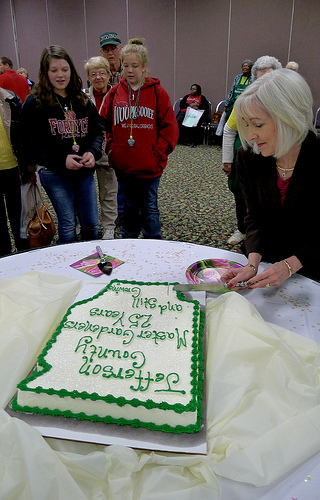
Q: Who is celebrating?
A: Jefferson County Master Gardeners.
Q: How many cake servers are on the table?
A: 1.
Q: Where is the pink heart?
A: On the girl to the left.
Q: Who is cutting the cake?
A: Woman on the right.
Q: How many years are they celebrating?
A: 25.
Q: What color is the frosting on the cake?
A: Green and white.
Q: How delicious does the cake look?
A: Very delicious.